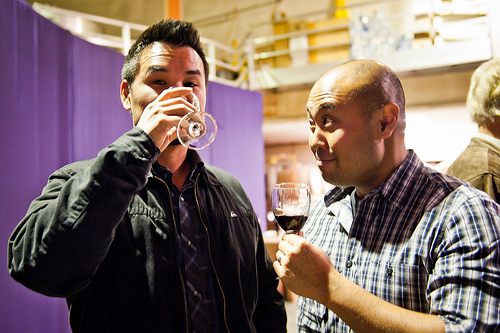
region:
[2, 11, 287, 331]
the man is drinking wine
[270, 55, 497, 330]
the man is holding wine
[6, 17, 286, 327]
purple wall behind the man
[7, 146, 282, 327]
man's jacket is green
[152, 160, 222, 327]
man's shirt is blue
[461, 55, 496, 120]
man's hair is gray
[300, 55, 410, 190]
the man is balding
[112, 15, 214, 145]
man's hair is black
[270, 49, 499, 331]
man is looking at other man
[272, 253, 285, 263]
man is wearing a ring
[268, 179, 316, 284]
a half full glass of wine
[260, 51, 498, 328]
a bald man in a collared shirt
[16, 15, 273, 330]
a man drinks from a glass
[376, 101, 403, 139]
a man's ear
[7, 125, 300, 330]
a long sleeved shirt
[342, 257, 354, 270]
a button on a shirt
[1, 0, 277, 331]
a long purple sheet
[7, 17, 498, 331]
two guys drinking together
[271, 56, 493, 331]
a man holding a glass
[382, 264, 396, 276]
a button to a shirt pocket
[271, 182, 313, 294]
a glass of wine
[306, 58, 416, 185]
a bald man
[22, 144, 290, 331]
a thin green jacket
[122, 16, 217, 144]
a man with spiked hair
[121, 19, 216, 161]
a man drinking a glass of wine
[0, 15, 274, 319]
a man in front of a purple curtain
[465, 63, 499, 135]
a man with gray hair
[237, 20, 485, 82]
a long white bannister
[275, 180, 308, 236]
a glass of red wine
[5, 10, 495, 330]
Man in the foreground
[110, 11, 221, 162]
Man has short dark hair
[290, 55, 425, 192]
Man has a bald head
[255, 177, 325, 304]
Man is holding a wine glass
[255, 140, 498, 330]
Man is wearing a button up shirt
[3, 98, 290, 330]
Man is wearing a light jacket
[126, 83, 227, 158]
Man is drinking from a wine glass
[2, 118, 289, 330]
The jacket is black in color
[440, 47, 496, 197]
A person in the background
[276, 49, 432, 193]
A side view of a man's head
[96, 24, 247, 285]
a man drinking from a wine glass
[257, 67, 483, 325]
a man holding a clear wine glass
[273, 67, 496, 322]
a man wearing a blue and white plaid shirt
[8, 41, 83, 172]
purple screen behind the men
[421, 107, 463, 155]
white wall of the room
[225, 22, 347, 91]
grey metal rails of the walkway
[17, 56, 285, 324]
a man wearing a black jacket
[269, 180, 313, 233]
a wine glass filled with red wine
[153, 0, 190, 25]
orange and white banner hanging from the ceiling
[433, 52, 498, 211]
a man wearing a brown jacket